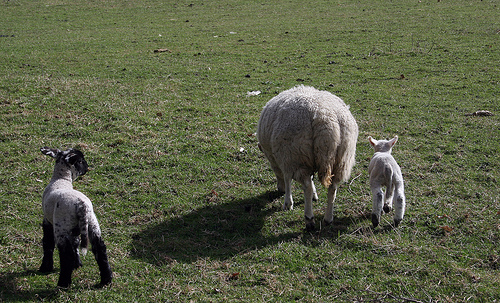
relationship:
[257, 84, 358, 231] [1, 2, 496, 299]
animal eating grass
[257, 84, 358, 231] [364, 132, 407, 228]
animal standing next to sheep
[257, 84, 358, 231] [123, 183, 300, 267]
animal casting shadow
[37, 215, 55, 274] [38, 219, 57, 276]
fur growing on leg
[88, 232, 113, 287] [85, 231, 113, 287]
fur growing on leg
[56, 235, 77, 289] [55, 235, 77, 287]
fur growing on leg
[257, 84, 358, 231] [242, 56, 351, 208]
animal growing on animal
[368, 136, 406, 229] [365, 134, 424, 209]
animal growing on animal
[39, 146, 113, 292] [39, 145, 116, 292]
animals growing on animal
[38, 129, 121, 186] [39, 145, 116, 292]
head belonging to animal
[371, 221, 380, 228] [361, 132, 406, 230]
feet belonging to sheep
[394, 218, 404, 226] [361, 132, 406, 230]
foot belonging to sheep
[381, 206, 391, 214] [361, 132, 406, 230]
foot belonging to sheep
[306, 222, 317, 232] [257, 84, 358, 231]
feet belonging to animal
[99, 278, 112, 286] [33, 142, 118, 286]
foot belonging to sheep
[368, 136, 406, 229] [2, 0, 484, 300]
animal standing in field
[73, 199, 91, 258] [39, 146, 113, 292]
tail belonging to animals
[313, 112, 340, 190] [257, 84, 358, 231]
lamb tail belonging to animal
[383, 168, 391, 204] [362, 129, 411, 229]
tail belonging to sheep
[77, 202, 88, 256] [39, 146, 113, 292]
tail belonging to animals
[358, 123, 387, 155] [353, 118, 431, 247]
ears belonging to lamb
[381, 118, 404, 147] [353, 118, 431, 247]
ears belonging to lamb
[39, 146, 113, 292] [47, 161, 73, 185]
animals has neck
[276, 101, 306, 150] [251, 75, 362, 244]
wool on sheep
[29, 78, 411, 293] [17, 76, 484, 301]
animals in foreground